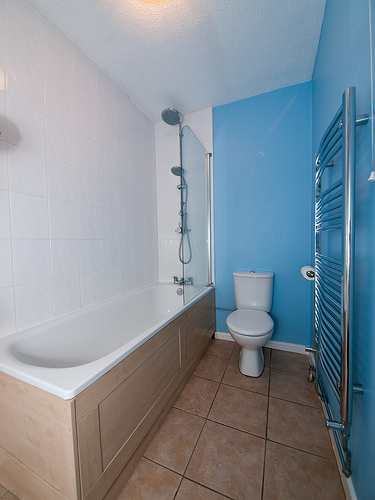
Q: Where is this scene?
A: Bathroom.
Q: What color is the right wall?
A: Blue.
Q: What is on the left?
A: Tub.